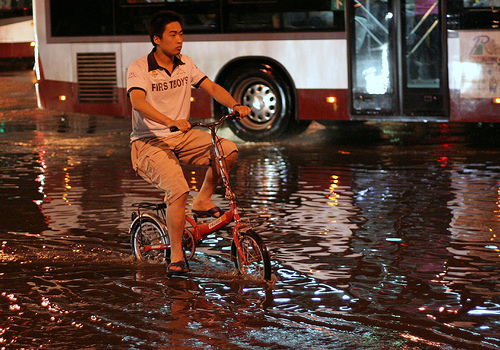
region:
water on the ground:
[370, 241, 468, 331]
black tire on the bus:
[229, 60, 290, 132]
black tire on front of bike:
[234, 227, 276, 280]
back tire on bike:
[134, 214, 169, 267]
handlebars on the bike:
[169, 111, 241, 138]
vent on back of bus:
[73, 50, 121, 104]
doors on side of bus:
[353, 2, 448, 117]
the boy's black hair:
[149, 12, 179, 37]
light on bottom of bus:
[58, 90, 69, 106]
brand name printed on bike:
[207, 213, 234, 228]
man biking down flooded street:
[111, 5, 296, 290]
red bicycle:
[122, 129, 283, 291]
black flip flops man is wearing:
[162, 199, 224, 279]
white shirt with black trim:
[129, 50, 208, 137]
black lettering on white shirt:
[148, 76, 190, 96]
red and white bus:
[30, 1, 499, 127]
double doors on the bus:
[349, 3, 445, 116]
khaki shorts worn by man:
[132, 123, 233, 194]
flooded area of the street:
[5, 123, 499, 348]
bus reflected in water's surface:
[27, 144, 498, 273]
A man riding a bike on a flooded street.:
[0, 13, 499, 349]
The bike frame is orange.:
[127, 105, 270, 284]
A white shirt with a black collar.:
[125, 49, 208, 141]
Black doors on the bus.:
[346, 0, 446, 116]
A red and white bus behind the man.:
[32, 0, 498, 140]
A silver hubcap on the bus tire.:
[240, 81, 276, 124]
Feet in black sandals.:
[165, 200, 230, 276]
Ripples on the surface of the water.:
[0, 106, 498, 347]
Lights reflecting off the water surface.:
[0, 120, 499, 349]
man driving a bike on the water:
[109, 11, 291, 306]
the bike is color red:
[117, 113, 277, 291]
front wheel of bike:
[229, 228, 277, 291]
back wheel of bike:
[123, 214, 176, 270]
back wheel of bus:
[201, 48, 301, 145]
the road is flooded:
[3, 83, 498, 345]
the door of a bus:
[342, 5, 455, 128]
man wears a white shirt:
[120, 13, 251, 278]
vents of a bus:
[68, 45, 125, 113]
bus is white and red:
[31, 0, 493, 133]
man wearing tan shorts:
[136, 139, 240, 206]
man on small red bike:
[215, 207, 245, 241]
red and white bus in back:
[309, 105, 326, 125]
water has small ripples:
[293, 201, 346, 303]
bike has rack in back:
[136, 190, 176, 235]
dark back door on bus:
[360, 32, 451, 134]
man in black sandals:
[176, 229, 192, 288]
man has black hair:
[141, 23, 198, 73]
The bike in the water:
[124, 98, 275, 287]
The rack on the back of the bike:
[132, 196, 168, 214]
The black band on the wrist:
[230, 100, 242, 110]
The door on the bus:
[351, 1, 443, 121]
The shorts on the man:
[128, 128, 238, 204]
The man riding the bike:
[126, 7, 250, 274]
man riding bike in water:
[110, 14, 266, 279]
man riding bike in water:
[103, 12, 298, 288]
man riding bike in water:
[116, 9, 295, 289]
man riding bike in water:
[106, 11, 286, 288]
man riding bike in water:
[109, 16, 286, 288]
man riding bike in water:
[101, 16, 288, 287]